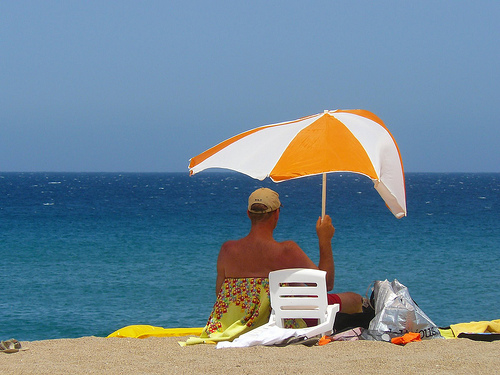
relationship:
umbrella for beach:
[188, 110, 406, 218] [3, 335, 499, 374]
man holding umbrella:
[216, 188, 364, 313] [188, 110, 406, 218]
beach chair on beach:
[268, 268, 340, 345] [3, 335, 499, 374]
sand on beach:
[0, 336, 499, 374] [3, 335, 499, 374]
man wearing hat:
[216, 188, 364, 313] [248, 186, 282, 213]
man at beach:
[216, 188, 364, 313] [3, 335, 499, 374]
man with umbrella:
[216, 188, 364, 313] [188, 110, 406, 218]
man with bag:
[216, 188, 364, 313] [361, 283, 445, 340]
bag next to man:
[361, 283, 445, 340] [216, 188, 364, 313]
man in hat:
[216, 188, 364, 313] [248, 186, 282, 213]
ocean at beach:
[1, 172, 499, 342] [3, 335, 499, 374]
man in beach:
[216, 188, 364, 313] [3, 335, 499, 374]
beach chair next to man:
[268, 268, 340, 345] [216, 188, 364, 313]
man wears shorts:
[216, 188, 364, 313] [330, 292, 342, 313]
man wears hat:
[216, 188, 364, 313] [248, 186, 282, 213]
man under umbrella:
[216, 188, 364, 313] [188, 110, 406, 218]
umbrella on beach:
[188, 110, 406, 218] [3, 335, 499, 374]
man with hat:
[216, 188, 364, 313] [248, 186, 282, 213]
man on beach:
[216, 188, 364, 313] [3, 335, 499, 374]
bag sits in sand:
[361, 283, 445, 340] [0, 336, 499, 374]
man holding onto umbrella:
[216, 188, 364, 313] [188, 110, 406, 218]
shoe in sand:
[0, 339, 28, 354] [0, 336, 499, 374]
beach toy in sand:
[107, 324, 206, 339] [0, 336, 499, 374]